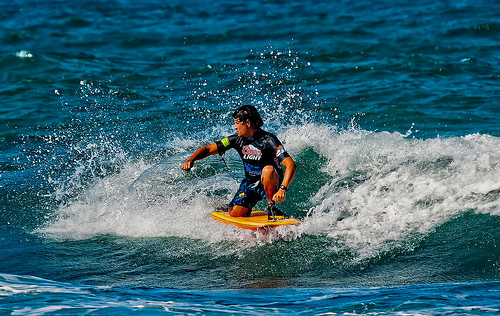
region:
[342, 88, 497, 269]
White crested wave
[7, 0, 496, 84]
Blue choppy sea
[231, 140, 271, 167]
Coors Light Sponsor Logo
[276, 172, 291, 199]
Black waterproof watch on surfers wrist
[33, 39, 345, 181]
Water splashes to the left and top of surfer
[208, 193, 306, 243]
Bright orange surfboard on the water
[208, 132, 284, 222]
Blue coiled surfer leash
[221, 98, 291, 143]
Face of left-facing black haired surfer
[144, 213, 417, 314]
Water in front of surfer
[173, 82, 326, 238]
Surfer kneeling on surfboard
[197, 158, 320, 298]
Person is on board in water.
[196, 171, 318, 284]
Board is yellow in color.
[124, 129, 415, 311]
Top of wave is white in color.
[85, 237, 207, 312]
Water is blue in color.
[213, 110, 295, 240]
Wet suit is mostly black.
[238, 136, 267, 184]
Coors light written on wet suit.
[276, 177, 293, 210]
Person has watch on wrist.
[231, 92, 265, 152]
Person has dark hair.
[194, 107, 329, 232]
Wet suit is short sleeved.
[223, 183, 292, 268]
One of person's knees are on the board.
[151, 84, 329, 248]
Coors Light logo on suit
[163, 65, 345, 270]
the wetsuit is blue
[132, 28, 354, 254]
this person has a watch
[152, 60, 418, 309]
the water is blue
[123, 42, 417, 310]
the spray is white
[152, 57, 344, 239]
the sport is surfing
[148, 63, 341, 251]
the surfboard is yellow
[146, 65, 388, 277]
the surfer is tan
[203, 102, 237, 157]
a green striped pad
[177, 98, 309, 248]
man kneeling on surfboard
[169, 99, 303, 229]
man in the ocean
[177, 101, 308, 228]
man wearing a wet suit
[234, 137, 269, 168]
Coors Light emblem on the mans wetsuit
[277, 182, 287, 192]
watch that the man is wearing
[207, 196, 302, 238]
dark yellow surfboard that the man is riding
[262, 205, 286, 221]
strap that keeps man attached to his surfboard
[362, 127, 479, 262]
foamy wave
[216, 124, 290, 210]
mans wetsuit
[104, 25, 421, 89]
crystal blue ocean water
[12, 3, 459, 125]
the water is blue.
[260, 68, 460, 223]
the waves are white.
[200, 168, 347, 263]
the surf board is orange.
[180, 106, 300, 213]
the wet suit is black.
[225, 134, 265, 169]
the logo is red and white.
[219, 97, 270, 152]
the boy's hair is black.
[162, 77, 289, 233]
the surfer is male.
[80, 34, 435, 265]
only one surfer.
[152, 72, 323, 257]
the surfer is riding a wave.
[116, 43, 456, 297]
the water is clear.